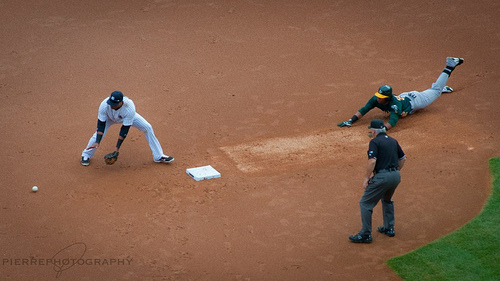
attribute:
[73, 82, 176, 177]
baseball player — ready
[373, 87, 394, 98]
helmet — green , hard 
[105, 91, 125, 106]
cap — dark blue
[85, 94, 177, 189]
uniform — white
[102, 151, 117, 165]
baseball glove — leather, right handed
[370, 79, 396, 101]
helmet — green and yellow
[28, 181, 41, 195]
baseball — rolling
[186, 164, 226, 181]
base — white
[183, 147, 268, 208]
base — white, square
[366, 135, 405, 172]
shirt — black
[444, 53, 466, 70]
cleats — high-top